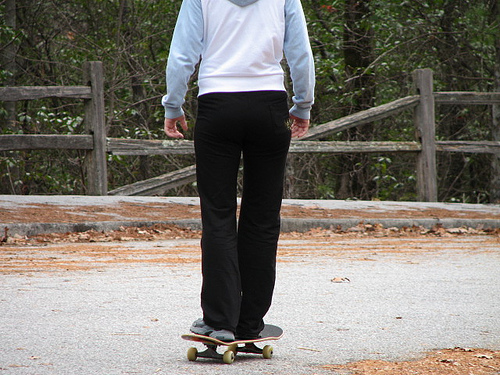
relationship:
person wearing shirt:
[162, 4, 319, 337] [164, 4, 332, 103]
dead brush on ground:
[338, 348, 498, 373] [4, 271, 149, 365]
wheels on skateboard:
[183, 344, 239, 370] [174, 323, 284, 349]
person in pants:
[162, 4, 319, 337] [181, 88, 278, 336]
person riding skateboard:
[162, 4, 319, 337] [174, 323, 284, 349]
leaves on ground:
[12, 230, 186, 244] [4, 271, 149, 365]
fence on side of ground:
[9, 61, 496, 223] [4, 271, 149, 365]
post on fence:
[75, 54, 118, 195] [9, 61, 496, 223]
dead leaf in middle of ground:
[325, 271, 352, 286] [4, 271, 149, 365]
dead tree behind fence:
[324, 2, 415, 198] [9, 61, 496, 223]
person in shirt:
[162, 4, 319, 337] [164, 4, 332, 103]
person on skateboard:
[162, 4, 319, 337] [174, 323, 284, 349]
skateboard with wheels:
[174, 323, 284, 349] [183, 344, 239, 370]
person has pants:
[162, 4, 319, 337] [181, 88, 278, 336]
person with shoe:
[162, 4, 319, 337] [183, 313, 233, 344]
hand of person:
[155, 110, 199, 142] [162, 4, 319, 337]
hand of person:
[280, 105, 312, 142] [162, 4, 319, 337]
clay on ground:
[24, 210, 88, 224] [4, 206, 499, 272]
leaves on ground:
[12, 230, 186, 244] [4, 206, 499, 272]